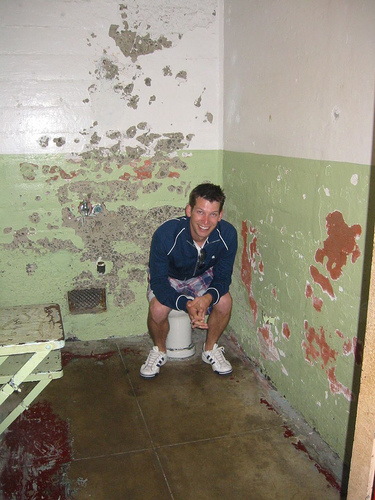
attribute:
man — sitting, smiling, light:
[136, 174, 245, 396]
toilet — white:
[154, 299, 200, 365]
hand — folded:
[185, 292, 213, 332]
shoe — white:
[137, 342, 169, 379]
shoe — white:
[204, 340, 232, 378]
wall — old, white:
[1, 3, 234, 292]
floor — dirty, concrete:
[19, 360, 347, 499]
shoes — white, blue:
[132, 349, 236, 378]